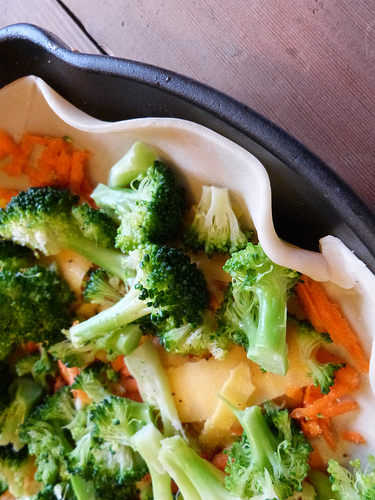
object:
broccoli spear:
[3, 254, 82, 365]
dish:
[17, 60, 372, 337]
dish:
[7, 12, 369, 463]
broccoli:
[80, 164, 188, 245]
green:
[142, 200, 158, 212]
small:
[326, 300, 330, 318]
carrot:
[299, 283, 369, 370]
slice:
[214, 362, 254, 409]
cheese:
[166, 355, 311, 419]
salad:
[2, 153, 220, 498]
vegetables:
[19, 185, 69, 257]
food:
[8, 276, 297, 498]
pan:
[57, 17, 193, 99]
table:
[197, 3, 359, 59]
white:
[184, 137, 217, 167]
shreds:
[300, 394, 347, 436]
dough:
[242, 376, 268, 395]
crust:
[24, 76, 90, 126]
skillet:
[48, 39, 132, 81]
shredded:
[28, 132, 91, 177]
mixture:
[66, 291, 264, 431]